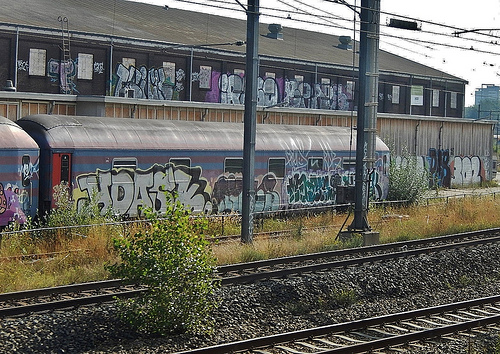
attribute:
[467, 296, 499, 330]
board — wooden 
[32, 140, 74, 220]
board — wooden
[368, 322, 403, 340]
board — wooden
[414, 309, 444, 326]
board — wooden